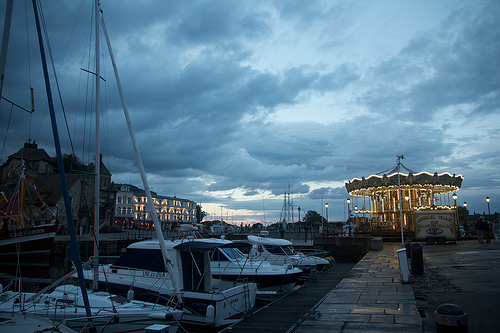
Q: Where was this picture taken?
A: At a marina.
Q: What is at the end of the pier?
A: A carousel.